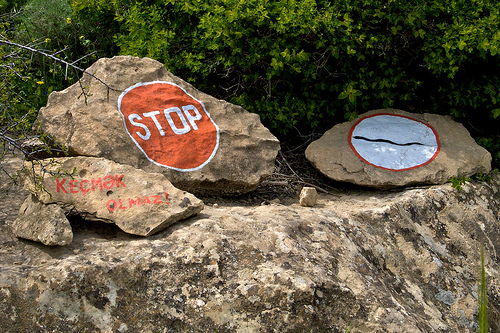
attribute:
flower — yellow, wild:
[34, 77, 43, 84]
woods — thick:
[0, 0, 499, 165]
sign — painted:
[346, 93, 449, 190]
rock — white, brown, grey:
[0, 162, 496, 331]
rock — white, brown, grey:
[302, 105, 497, 183]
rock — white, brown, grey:
[18, 152, 207, 253]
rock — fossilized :
[15, 55, 485, 331]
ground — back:
[337, 185, 356, 216]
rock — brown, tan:
[298, 96, 495, 198]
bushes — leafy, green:
[1, 2, 498, 124]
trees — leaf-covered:
[7, 0, 497, 140]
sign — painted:
[298, 90, 468, 180]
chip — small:
[297, 184, 319, 209]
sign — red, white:
[117, 79, 220, 172]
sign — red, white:
[346, 112, 441, 172]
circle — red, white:
[347, 110, 439, 172]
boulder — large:
[30, 51, 284, 198]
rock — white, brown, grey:
[37, 54, 279, 194]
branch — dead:
[2, 35, 124, 104]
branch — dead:
[2, 122, 65, 186]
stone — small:
[297, 183, 317, 206]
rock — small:
[299, 179, 321, 214]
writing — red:
[49, 175, 174, 217]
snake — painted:
[352, 135, 428, 147]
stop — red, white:
[102, 65, 233, 175]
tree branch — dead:
[9, 20, 120, 107]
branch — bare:
[8, 40, 123, 100]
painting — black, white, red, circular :
[349, 110, 442, 172]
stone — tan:
[297, 182, 322, 207]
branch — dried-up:
[169, 24, 353, 126]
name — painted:
[4, 149, 209, 246]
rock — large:
[49, 211, 497, 323]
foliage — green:
[206, 2, 436, 79]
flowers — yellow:
[23, 10, 106, 89]